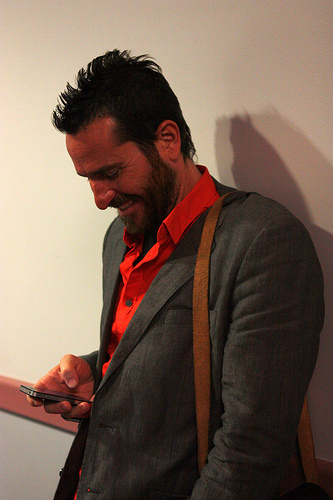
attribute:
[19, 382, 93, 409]
mobile phone — small, black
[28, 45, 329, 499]
man — smiling, dark haired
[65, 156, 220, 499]
shirt — red, orange, collared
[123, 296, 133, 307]
button — small, grey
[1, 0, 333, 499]
wall — white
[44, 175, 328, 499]
blazer — grey, gray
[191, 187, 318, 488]
strap — brown, long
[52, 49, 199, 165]
hair — styled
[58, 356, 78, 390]
thumb — bent